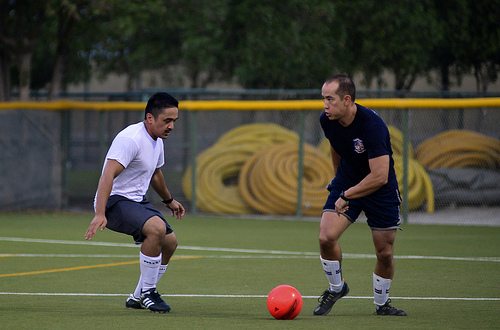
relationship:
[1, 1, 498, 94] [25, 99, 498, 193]
tree tops behind green fencing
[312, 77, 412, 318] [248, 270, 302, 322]
player kicking ball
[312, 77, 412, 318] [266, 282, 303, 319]
player with ball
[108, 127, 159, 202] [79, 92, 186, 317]
white shirt on players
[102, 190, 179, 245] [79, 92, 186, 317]
gray shorts on players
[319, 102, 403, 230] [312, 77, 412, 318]
navy uniform on player